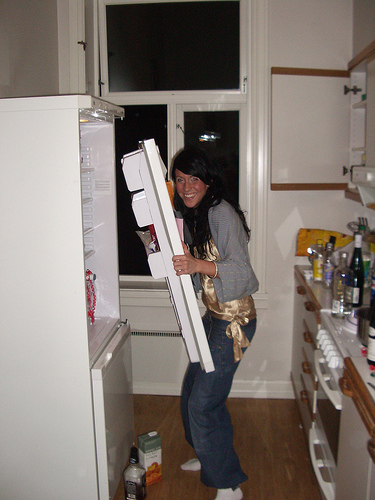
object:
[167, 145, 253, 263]
hair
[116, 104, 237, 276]
window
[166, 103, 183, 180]
panel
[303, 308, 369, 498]
cooker unit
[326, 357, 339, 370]
knob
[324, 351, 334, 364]
knob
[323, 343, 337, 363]
knob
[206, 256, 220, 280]
bracelet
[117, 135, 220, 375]
door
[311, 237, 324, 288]
bottle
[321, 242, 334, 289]
bottle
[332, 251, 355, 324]
bottle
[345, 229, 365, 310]
bottle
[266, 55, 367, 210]
door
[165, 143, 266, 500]
girl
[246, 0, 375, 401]
wall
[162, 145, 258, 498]
woman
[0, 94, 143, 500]
refrigerator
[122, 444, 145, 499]
bottle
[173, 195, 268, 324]
shirt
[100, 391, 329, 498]
floor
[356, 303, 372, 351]
pot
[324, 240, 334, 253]
top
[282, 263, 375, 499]
cabinet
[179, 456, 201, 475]
socks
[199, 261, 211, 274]
wrist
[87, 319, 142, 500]
door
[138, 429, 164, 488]
juice